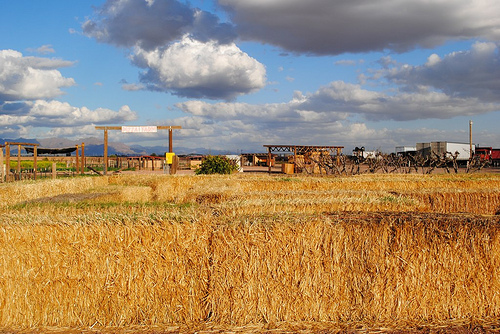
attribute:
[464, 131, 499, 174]
truck — bright red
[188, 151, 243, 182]
bush — green , large 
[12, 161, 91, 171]
grass — green 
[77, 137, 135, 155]
mountains — distant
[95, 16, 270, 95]
clouds — dark 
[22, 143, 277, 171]
mountains — long , blue , grey 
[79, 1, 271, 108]
clouds — fluffy , little 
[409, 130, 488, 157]
trailer — white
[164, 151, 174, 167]
sign — yellow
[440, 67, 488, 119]
cloud — gray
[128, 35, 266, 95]
cloud — white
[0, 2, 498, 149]
blue skies — blue 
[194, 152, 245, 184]
bush — green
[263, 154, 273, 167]
post — brown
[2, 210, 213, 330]
hay — yellow tan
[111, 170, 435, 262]
ranchland — vibrant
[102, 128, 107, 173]
pole — wooden 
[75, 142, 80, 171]
pole — wooden 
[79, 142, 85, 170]
pole — wooden 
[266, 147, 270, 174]
pole — wooden 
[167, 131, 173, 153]
pole — wooden 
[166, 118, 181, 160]
pole — brown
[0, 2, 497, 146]
sky — blue 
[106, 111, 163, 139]
sign — white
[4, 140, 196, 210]
plants — green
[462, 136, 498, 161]
cab — bright red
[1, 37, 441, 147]
clouds — white 